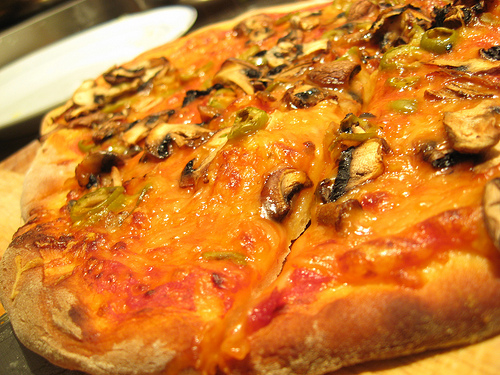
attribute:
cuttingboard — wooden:
[344, 342, 499, 374]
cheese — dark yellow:
[378, 177, 471, 232]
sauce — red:
[248, 265, 332, 332]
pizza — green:
[16, 9, 492, 355]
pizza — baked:
[91, 54, 471, 305]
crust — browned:
[225, 273, 493, 348]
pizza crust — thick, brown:
[0, 133, 499, 372]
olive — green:
[419, 25, 459, 56]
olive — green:
[387, 71, 420, 90]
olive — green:
[222, 103, 272, 144]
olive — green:
[62, 178, 128, 225]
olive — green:
[74, 133, 99, 153]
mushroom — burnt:
[262, 171, 311, 221]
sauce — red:
[75, 255, 200, 322]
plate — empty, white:
[1, 4, 198, 139]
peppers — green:
[65, 173, 147, 228]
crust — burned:
[246, 220, 467, 357]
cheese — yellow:
[35, 145, 353, 332]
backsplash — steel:
[0, 0, 140, 58]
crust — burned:
[5, 207, 59, 257]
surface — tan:
[399, 344, 484, 370]